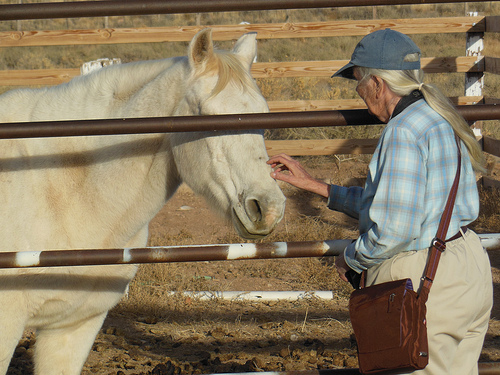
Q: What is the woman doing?
A: Petting a horse.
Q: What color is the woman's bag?
A: Brown.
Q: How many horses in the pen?
A: One.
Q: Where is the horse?
A: In the pen.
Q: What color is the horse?
A: White.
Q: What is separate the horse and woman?
A: Metal bars.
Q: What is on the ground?
A: Manure.